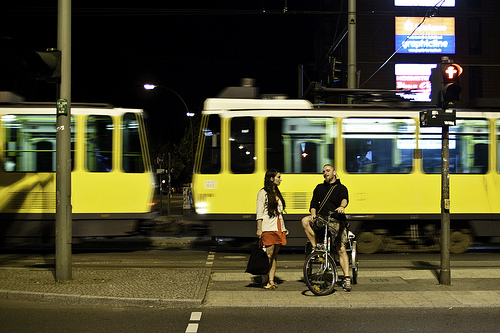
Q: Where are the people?
A: On the sidewalk.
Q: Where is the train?
A: Behind the people.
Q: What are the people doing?
A: Talking.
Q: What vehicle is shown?
A: Train.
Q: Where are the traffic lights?
A: By the people.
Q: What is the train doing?
A: Moving.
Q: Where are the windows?
A: On the train.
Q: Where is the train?
A: On the tracks.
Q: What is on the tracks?
A: The train.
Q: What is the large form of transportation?
A: Train.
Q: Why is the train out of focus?
A: It is moving.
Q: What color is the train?
A: Yellow.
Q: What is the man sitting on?
A: Bike.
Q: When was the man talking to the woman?
A: Nighttime.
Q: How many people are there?
A: Two.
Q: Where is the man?
A: On the bike.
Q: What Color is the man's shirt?
A: Black.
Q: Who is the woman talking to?
A: The man.